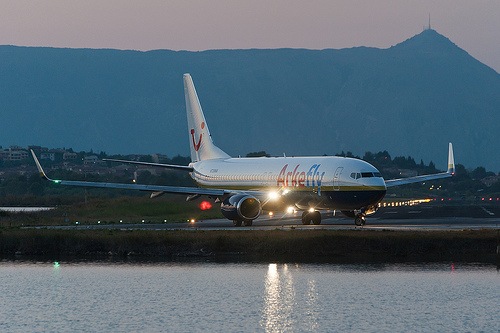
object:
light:
[267, 189, 279, 198]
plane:
[30, 72, 455, 224]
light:
[288, 206, 294, 214]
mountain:
[0, 29, 499, 174]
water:
[0, 264, 500, 333]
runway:
[17, 209, 499, 229]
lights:
[377, 203, 381, 207]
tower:
[428, 14, 432, 30]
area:
[0, 29, 499, 174]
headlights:
[307, 206, 314, 213]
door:
[333, 165, 344, 191]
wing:
[383, 142, 456, 195]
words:
[304, 163, 326, 196]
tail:
[181, 74, 229, 164]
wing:
[29, 148, 225, 196]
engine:
[221, 193, 262, 221]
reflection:
[260, 261, 317, 332]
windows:
[322, 176, 324, 179]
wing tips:
[27, 149, 56, 184]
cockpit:
[348, 160, 389, 191]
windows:
[362, 172, 374, 177]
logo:
[190, 121, 208, 152]